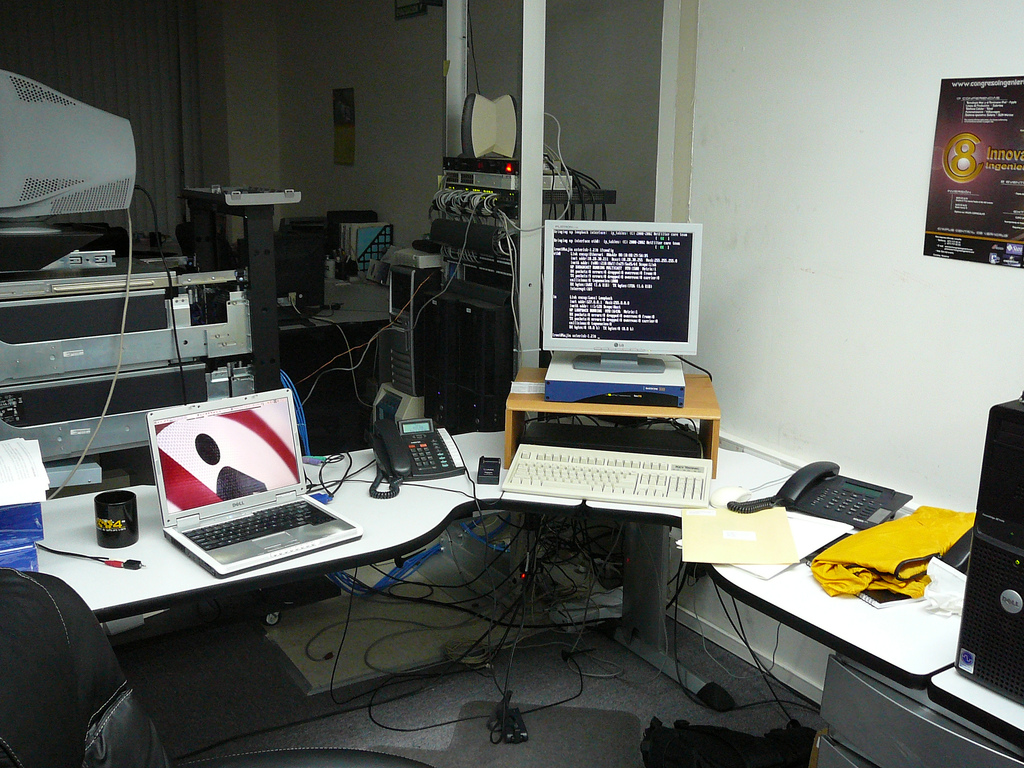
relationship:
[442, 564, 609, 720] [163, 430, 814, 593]
cords below a desk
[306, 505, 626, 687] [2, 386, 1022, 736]
wires under desk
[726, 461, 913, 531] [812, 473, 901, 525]
phone with features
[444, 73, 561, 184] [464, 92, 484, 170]
speakers with facing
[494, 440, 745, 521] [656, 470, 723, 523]
keyboard with pad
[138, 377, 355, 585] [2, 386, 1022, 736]
laptop on desk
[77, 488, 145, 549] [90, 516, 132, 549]
mug with writing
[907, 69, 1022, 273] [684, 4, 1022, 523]
flyer on wall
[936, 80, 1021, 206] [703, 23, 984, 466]
poster on wall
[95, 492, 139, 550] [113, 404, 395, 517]
mug with design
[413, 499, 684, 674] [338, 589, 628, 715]
wires on floor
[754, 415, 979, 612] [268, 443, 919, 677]
phone on desk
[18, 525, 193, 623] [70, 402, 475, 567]
cord on desk